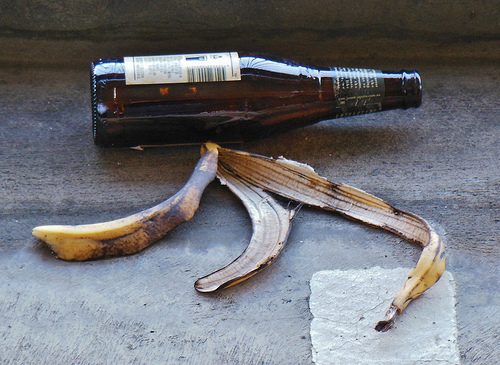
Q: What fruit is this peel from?
A: A banana.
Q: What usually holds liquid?
A: Bottle.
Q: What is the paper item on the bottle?
A: A label.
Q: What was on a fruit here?
A: Banana peel.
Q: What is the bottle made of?
A: Glass.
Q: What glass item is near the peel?
A: A bottle.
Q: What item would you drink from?
A: Bottle.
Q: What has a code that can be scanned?
A: Label.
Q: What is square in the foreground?
A: A white patch on a surface.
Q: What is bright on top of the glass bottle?
A: A reflection of light.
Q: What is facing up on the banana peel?
A: The inside portion.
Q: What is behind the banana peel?
A: A bottle on the ground.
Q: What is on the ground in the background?
A: A bottle on the ground.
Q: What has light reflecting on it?
A: The bottle on the ground.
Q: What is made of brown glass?
A: A bottle on the ground.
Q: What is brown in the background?
A: A glass bottle.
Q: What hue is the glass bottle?
A: Brown.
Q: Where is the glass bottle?
A: Next to the banana peel.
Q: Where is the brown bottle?
A: Laying on it's side.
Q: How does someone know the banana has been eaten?
A: It's an empty peel.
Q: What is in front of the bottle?
A: A banana peel.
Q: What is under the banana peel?
A: A white square.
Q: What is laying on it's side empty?
A: A beer bottle.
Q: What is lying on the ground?
A: An empty beer bottle and a banana peel.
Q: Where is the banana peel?
A: On the street.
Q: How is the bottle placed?
A: On its side.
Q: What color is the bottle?
A: Brown.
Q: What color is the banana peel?
A: Yellow and brown.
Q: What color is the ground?
A: Gray.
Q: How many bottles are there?
A: One.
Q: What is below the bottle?
A: The banana peel.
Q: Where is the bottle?
A: Above the banana peel.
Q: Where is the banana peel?
A: Beneath the bottle.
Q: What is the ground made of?
A: Cement.